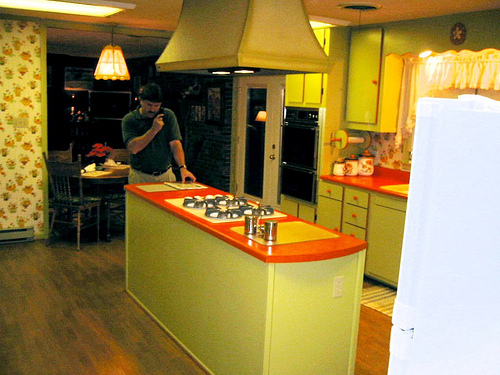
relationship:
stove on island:
[166, 190, 288, 225] [120, 184, 361, 374]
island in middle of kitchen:
[120, 184, 361, 374] [0, 10, 496, 371]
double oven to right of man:
[280, 107, 315, 200] [124, 73, 197, 205]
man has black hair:
[121, 83, 196, 184] [138, 85, 164, 101]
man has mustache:
[121, 83, 196, 184] [138, 108, 157, 116]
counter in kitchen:
[127, 184, 370, 264] [0, 10, 496, 371]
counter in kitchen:
[325, 157, 415, 205] [0, 10, 496, 371]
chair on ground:
[42, 151, 100, 251] [0, 231, 397, 372]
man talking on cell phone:
[121, 83, 196, 184] [157, 99, 170, 124]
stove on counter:
[166, 190, 288, 225] [117, 171, 374, 264]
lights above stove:
[209, 67, 262, 87] [172, 184, 281, 230]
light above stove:
[98, 49, 127, 75] [172, 184, 281, 230]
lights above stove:
[409, 44, 462, 80] [172, 184, 281, 230]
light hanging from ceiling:
[92, 43, 131, 80] [0, 0, 498, 32]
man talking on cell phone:
[120, 81, 197, 186] [159, 106, 165, 118]